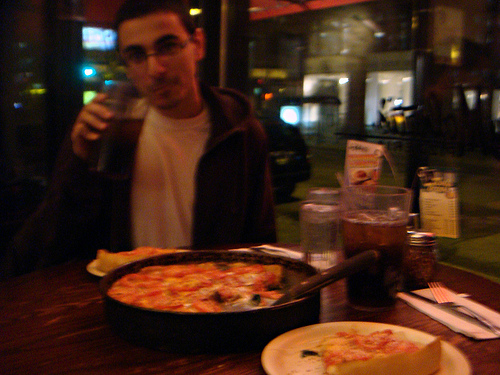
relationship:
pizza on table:
[121, 258, 286, 312] [4, 237, 499, 374]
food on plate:
[315, 326, 441, 374] [258, 320, 475, 373]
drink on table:
[342, 185, 397, 305] [4, 237, 499, 374]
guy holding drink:
[9, 0, 278, 281] [97, 75, 141, 169]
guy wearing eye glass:
[9, 0, 278, 281] [117, 34, 195, 67]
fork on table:
[438, 280, 494, 335] [4, 237, 499, 374]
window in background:
[303, 70, 348, 124] [212, 4, 495, 94]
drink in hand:
[97, 75, 141, 169] [75, 97, 107, 143]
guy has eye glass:
[9, 0, 278, 281] [117, 34, 195, 67]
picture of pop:
[2, 3, 500, 369] [340, 193, 406, 309]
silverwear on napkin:
[411, 277, 493, 330] [399, 276, 500, 337]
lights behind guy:
[248, 71, 273, 106] [9, 0, 278, 281]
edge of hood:
[243, 87, 253, 127] [210, 82, 254, 130]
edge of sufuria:
[104, 268, 132, 327] [86, 251, 322, 327]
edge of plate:
[89, 261, 104, 274] [87, 250, 131, 274]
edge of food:
[99, 249, 137, 261] [96, 246, 174, 257]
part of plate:
[83, 260, 102, 277] [87, 250, 131, 274]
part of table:
[5, 277, 48, 361] [4, 237, 499, 374]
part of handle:
[328, 248, 387, 272] [260, 247, 381, 287]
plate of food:
[258, 320, 475, 373] [315, 333, 432, 374]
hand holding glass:
[75, 97, 107, 143] [94, 79, 146, 170]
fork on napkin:
[438, 280, 494, 335] [399, 276, 500, 337]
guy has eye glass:
[9, 0, 278, 281] [120, 39, 196, 57]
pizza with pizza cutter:
[121, 258, 286, 312] [235, 238, 386, 312]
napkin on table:
[399, 276, 500, 337] [4, 237, 499, 374]